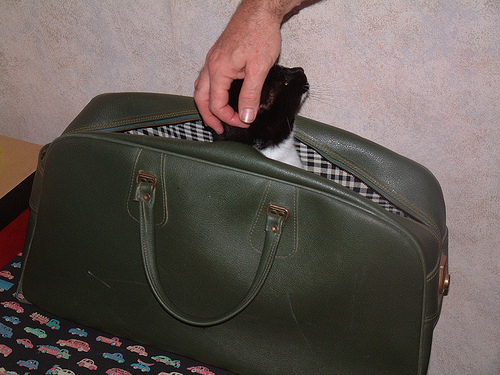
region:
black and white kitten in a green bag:
[216, 65, 308, 169]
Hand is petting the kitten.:
[193, 0, 303, 130]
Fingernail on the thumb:
[240, 108, 255, 121]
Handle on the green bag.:
[133, 182, 280, 329]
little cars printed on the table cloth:
[0, 252, 222, 372]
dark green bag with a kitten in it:
[23, 92, 448, 374]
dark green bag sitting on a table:
[27, 92, 448, 372]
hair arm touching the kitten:
[196, 0, 301, 128]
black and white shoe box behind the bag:
[0, 135, 40, 268]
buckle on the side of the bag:
[439, 254, 449, 298]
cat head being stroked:
[198, 54, 341, 184]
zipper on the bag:
[277, 133, 411, 201]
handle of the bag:
[112, 188, 292, 340]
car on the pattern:
[53, 335, 93, 352]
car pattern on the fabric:
[1, 313, 141, 370]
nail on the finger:
[233, 103, 258, 129]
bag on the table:
[0, 90, 450, 373]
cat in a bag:
[31, 59, 473, 364]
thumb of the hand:
[228, 34, 283, 129]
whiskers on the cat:
[305, 83, 342, 108]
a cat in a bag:
[12, 10, 477, 353]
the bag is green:
[89, 98, 351, 370]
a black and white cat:
[210, 47, 348, 181]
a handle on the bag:
[97, 124, 284, 372]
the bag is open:
[110, 74, 451, 285]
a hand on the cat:
[175, 7, 333, 142]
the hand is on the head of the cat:
[200, 18, 322, 163]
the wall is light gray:
[356, 40, 466, 121]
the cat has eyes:
[275, 75, 300, 90]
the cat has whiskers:
[260, 57, 340, 139]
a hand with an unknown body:
[193, 0, 335, 137]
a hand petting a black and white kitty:
[185, 1, 317, 147]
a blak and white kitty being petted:
[182, 8, 331, 180]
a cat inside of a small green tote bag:
[17, 53, 449, 373]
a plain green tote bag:
[18, 90, 453, 373]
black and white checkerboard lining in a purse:
[106, 107, 418, 224]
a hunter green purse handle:
[133, 168, 290, 332]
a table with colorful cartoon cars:
[1, 247, 241, 374]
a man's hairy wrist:
[223, 0, 311, 30]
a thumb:
[231, 100, 263, 131]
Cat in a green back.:
[17, 52, 451, 367]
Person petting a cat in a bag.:
[194, 11, 316, 191]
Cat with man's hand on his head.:
[191, 9, 318, 168]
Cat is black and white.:
[216, 65, 316, 173]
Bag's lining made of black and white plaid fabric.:
[140, 122, 397, 184]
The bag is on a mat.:
[3, 86, 454, 371]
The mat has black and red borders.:
[2, 165, 43, 371]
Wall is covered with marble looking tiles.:
[5, 6, 195, 86]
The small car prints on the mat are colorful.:
[3, 310, 110, 370]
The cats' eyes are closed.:
[277, 72, 293, 88]